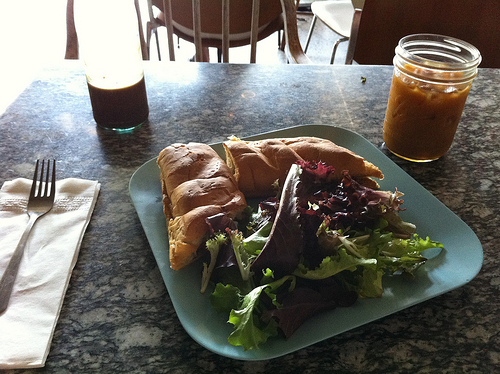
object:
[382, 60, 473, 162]
beverage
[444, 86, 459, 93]
ice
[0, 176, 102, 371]
napkin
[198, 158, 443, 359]
lettuce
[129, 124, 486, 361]
plate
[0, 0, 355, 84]
ground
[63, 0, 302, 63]
backing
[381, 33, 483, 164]
container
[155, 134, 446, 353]
food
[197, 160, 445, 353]
salad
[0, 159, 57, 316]
fork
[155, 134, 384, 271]
bread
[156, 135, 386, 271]
sandwich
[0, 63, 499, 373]
top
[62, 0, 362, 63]
chair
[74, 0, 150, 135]
container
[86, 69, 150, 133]
salad dressing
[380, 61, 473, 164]
dressing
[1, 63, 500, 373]
table